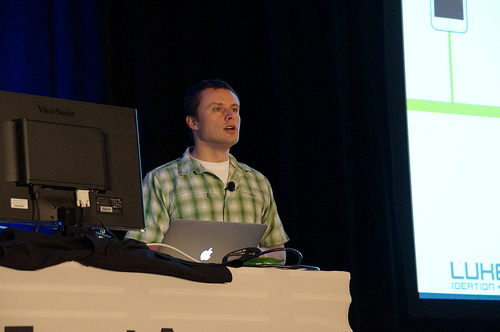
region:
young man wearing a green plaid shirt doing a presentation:
[105, 62, 338, 289]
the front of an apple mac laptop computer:
[156, 214, 269, 266]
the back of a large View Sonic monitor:
[3, 87, 148, 237]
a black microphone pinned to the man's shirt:
[222, 175, 242, 193]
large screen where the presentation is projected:
[381, 7, 498, 297]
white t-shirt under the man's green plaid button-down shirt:
[195, 158, 234, 184]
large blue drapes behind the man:
[3, 7, 135, 89]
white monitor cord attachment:
[69, 190, 95, 211]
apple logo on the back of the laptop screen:
[200, 243, 215, 258]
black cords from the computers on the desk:
[232, 243, 324, 270]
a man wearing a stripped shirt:
[130, 66, 308, 265]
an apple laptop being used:
[155, 207, 267, 266]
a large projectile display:
[340, 0, 499, 325]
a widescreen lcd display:
[0, 92, 158, 236]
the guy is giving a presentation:
[131, 72, 303, 267]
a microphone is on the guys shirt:
[211, 172, 246, 199]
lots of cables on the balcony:
[210, 242, 328, 277]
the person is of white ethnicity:
[130, 75, 298, 266]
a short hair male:
[126, 72, 300, 269]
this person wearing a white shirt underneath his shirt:
[121, 74, 303, 264]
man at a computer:
[187, 83, 258, 252]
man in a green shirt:
[186, 100, 260, 210]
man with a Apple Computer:
[173, 105, 272, 262]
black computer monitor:
[36, 103, 173, 243]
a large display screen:
[313, 11, 478, 310]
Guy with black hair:
[184, 69, 254, 157]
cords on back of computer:
[27, 159, 324, 273]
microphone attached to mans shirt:
[203, 178, 260, 224]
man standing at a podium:
[120, 63, 358, 329]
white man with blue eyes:
[197, 83, 259, 148]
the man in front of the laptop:
[122, 78, 288, 265]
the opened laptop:
[157, 220, 267, 265]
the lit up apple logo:
[199, 247, 213, 260]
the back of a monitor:
[0, 90, 145, 230]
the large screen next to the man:
[401, 0, 498, 300]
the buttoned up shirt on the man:
[125, 145, 290, 245]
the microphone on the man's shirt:
[223, 179, 235, 191]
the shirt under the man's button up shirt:
[187, 153, 229, 188]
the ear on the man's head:
[185, 113, 198, 130]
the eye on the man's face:
[211, 104, 223, 112]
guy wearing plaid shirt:
[122, 76, 290, 266]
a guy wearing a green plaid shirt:
[133, 79, 293, 271]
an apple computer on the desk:
[156, 216, 269, 266]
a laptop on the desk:
[155, 218, 269, 266]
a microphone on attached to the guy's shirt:
[224, 180, 236, 190]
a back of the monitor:
[0, 91, 150, 241]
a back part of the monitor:
[1, 88, 148, 233]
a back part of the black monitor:
[3, 92, 145, 232]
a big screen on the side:
[378, 1, 498, 320]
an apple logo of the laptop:
[197, 244, 214, 260]